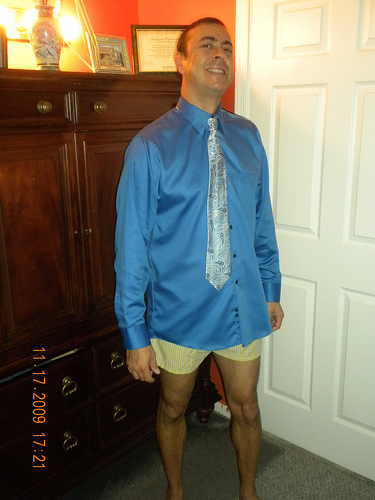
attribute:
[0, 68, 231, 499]
dresser — brown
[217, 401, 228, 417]
base board — white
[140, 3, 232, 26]
wall — orange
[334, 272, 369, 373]
door — white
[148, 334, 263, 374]
shorts — beige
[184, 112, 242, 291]
tie — Light gray paisley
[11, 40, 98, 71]
board — white, base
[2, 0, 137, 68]
wall — orange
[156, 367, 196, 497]
man's leg — Man's muscular long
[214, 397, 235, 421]
board — White base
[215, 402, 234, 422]
base — White base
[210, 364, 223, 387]
wall — orange 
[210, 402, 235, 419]
baseboard — white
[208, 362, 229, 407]
wall — orange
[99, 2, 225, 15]
wall — orange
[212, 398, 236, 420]
board — white, base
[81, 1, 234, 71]
wall — orange 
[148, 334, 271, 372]
shorts — yellow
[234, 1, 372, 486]
door — bedroom   , Decorative rectangular indentations 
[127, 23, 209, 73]
paper — recognition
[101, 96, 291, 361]
shirt — blue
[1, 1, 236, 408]
wall — orange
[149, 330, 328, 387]
drawer — open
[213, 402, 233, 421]
base board — white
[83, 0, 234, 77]
wall — orange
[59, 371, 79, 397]
handle — gold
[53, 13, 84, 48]
light — on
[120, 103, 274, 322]
shirt — blue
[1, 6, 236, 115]
bedroom — man's  